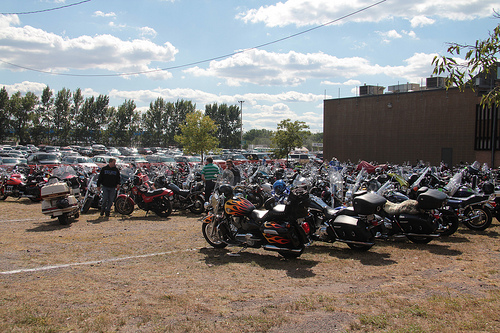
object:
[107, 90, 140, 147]
tree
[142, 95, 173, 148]
tree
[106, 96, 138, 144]
tree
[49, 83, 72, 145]
tree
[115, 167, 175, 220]
motorcycle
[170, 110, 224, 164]
green tree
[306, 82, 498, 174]
building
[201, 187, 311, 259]
motorcycle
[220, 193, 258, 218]
flames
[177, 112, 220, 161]
tree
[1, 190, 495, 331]
field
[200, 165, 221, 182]
shirt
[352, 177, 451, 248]
motorcycle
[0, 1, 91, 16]
power lines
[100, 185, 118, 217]
blue jeans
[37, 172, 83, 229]
motorcycle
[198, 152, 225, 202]
man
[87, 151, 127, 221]
man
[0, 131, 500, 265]
parking lot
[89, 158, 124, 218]
sweater